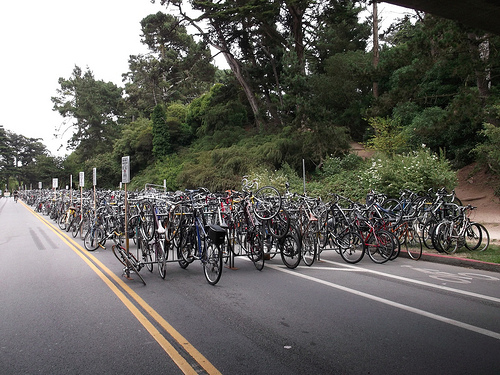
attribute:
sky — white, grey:
[0, 0, 235, 163]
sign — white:
[120, 155, 131, 183]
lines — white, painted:
[234, 235, 498, 339]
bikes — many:
[16, 180, 491, 284]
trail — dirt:
[446, 159, 498, 234]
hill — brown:
[133, 124, 499, 238]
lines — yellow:
[116, 285, 218, 373]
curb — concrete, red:
[386, 244, 498, 276]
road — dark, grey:
[17, 277, 117, 336]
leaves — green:
[393, 59, 433, 101]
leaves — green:
[317, 35, 342, 85]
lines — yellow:
[14, 193, 239, 370]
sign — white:
[89, 165, 99, 186]